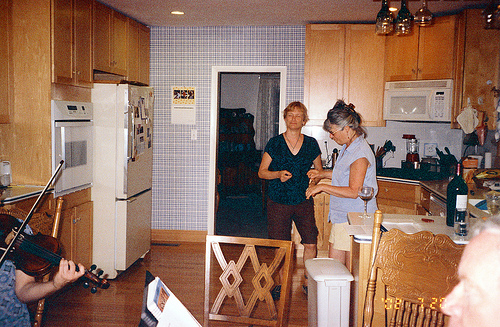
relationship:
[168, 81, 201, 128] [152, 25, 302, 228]
calendar on wall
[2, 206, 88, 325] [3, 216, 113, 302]
person playing violin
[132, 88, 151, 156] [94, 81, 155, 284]
photos on fridge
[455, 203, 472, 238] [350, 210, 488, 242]
wine glass on countertop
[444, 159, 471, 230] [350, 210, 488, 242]
bottle on countertop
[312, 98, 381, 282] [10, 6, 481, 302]
woman dancing in kitchen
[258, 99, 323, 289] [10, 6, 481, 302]
woman dancing in kitchen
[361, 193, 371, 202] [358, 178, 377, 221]
red wine in glass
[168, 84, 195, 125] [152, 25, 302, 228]
calendar on wall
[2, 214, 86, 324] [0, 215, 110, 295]
child playing violin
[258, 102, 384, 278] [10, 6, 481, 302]
women in kitchen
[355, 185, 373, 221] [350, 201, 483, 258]
glass on table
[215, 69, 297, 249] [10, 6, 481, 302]
door in kitchen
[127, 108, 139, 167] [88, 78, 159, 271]
handle grip on refrigerator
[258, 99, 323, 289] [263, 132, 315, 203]
woman in shirt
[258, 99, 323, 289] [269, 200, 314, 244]
woman in shorts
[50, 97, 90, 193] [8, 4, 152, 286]
oven in wall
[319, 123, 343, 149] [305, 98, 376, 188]
face of a woman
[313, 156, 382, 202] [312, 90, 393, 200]
arm of a woman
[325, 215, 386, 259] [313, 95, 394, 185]
shorts of a woman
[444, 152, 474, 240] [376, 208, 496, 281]
bottle sitting on counter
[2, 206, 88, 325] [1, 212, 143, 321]
person playing violin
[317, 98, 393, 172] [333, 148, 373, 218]
woman in a shirt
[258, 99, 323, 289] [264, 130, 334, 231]
woman in a shirt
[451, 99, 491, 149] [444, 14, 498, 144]
pot holders hanging from cabinet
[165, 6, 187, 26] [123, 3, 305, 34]
recessed light in ceiling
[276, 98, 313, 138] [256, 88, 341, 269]
head of a woman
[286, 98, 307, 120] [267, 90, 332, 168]
hair of a woman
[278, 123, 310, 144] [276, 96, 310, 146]
neck of a woman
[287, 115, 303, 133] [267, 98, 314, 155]
mouth of a woman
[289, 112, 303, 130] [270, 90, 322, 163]
nose of a woman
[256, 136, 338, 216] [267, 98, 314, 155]
shirt of a woman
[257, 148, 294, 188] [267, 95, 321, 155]
right arm of a woman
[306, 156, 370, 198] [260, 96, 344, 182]
arm of a woman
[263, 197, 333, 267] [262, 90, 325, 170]
shorts of a woman